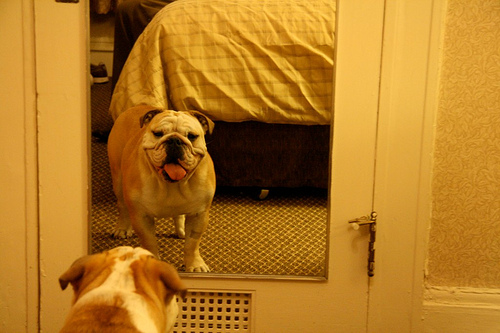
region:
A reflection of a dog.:
[104, 102, 218, 274]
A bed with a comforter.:
[101, 2, 338, 129]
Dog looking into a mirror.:
[50, 241, 192, 331]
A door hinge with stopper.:
[345, 207, 382, 281]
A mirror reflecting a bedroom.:
[80, 1, 342, 284]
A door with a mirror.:
[25, 0, 450, 330]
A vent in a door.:
[164, 284, 266, 329]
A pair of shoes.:
[81, 54, 111, 91]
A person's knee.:
[107, 0, 175, 102]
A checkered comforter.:
[106, 0, 339, 132]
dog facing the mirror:
[59, 245, 183, 332]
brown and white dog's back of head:
[59, 248, 184, 332]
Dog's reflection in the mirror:
[108, 105, 213, 272]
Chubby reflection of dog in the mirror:
[108, 108, 216, 273]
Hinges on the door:
[352, 206, 379, 278]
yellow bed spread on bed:
[111, 0, 333, 117]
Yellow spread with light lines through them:
[111, 0, 333, 124]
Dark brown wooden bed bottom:
[205, 120, 331, 190]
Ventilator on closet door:
[174, 290, 249, 329]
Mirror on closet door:
[88, 0, 333, 277]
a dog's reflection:
[98, 101, 220, 246]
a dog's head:
[47, 240, 188, 330]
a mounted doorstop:
[337, 201, 377, 232]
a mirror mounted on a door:
[72, 1, 345, 287]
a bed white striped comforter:
[95, 0, 336, 131]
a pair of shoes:
[86, 53, 107, 84]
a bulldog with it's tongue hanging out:
[102, 95, 227, 275]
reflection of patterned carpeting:
[205, 200, 325, 271]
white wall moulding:
[415, 280, 496, 330]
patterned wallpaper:
[434, 5, 493, 284]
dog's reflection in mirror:
[106, 100, 216, 273]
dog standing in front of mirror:
[58, 242, 186, 332]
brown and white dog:
[58, 243, 187, 329]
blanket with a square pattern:
[105, 0, 337, 125]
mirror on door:
[30, 0, 387, 331]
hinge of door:
[349, 208, 380, 280]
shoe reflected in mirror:
[88, 59, 107, 84]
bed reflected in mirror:
[106, 1, 331, 169]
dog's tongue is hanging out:
[106, 106, 216, 273]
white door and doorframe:
[3, 0, 499, 331]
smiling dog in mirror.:
[132, 98, 253, 226]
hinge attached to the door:
[344, 207, 384, 282]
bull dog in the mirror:
[87, 68, 252, 310]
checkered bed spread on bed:
[96, 3, 351, 138]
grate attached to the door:
[110, 286, 279, 331]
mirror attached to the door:
[51, 2, 351, 318]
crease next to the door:
[10, 2, 60, 321]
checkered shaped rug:
[182, 217, 318, 296]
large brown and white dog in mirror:
[79, 93, 232, 284]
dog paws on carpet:
[117, 186, 256, 320]